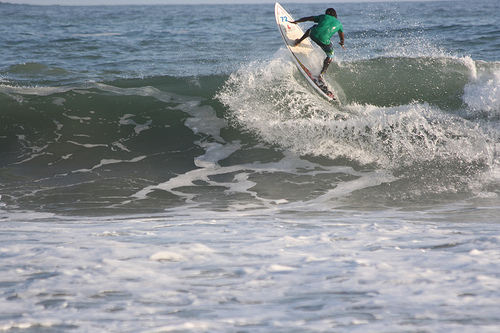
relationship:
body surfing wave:
[289, 7, 346, 81] [15, 43, 498, 176]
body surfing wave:
[289, 7, 346, 81] [1, 50, 497, 180]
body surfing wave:
[289, 7, 346, 81] [5, 52, 499, 161]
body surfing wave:
[289, 7, 346, 81] [10, 45, 497, 166]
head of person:
[322, 4, 341, 20] [284, 6, 345, 77]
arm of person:
[337, 28, 345, 46] [288, 8, 350, 80]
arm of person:
[291, 11, 321, 26] [292, 3, 344, 78]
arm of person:
[335, 28, 346, 48] [291, 3, 347, 86]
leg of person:
[318, 43, 331, 73] [291, 7, 351, 71]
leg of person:
[289, 28, 311, 47] [288, 3, 347, 80]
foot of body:
[295, 36, 303, 46] [289, 7, 346, 81]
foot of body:
[295, 38, 301, 46] [289, 7, 346, 81]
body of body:
[311, 14, 343, 46] [289, 7, 346, 81]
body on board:
[289, 7, 346, 81] [272, 2, 341, 104]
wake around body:
[216, 47, 493, 161] [289, 7, 346, 81]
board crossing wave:
[272, 2, 341, 104] [0, 56, 498, 205]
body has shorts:
[289, 7, 346, 81] [308, 26, 334, 57]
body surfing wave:
[289, 7, 346, 81] [0, 56, 498, 205]